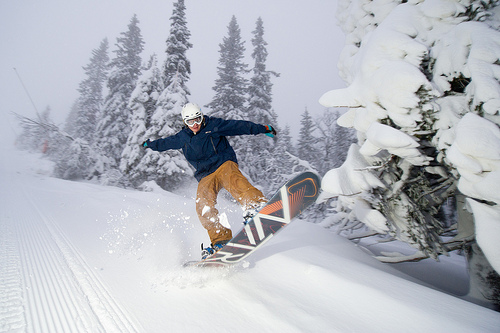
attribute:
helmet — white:
[175, 99, 204, 122]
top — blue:
[124, 114, 273, 174]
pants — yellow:
[191, 163, 264, 247]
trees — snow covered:
[21, 13, 302, 202]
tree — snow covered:
[309, 5, 496, 297]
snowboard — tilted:
[183, 160, 320, 283]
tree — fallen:
[10, 101, 107, 184]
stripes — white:
[233, 213, 282, 258]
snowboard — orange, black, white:
[184, 170, 319, 270]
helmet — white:
[175, 104, 201, 123]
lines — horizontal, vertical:
[4, 170, 164, 330]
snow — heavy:
[360, 41, 406, 121]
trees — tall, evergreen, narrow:
[17, 5, 201, 187]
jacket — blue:
[142, 108, 271, 184]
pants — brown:
[188, 161, 262, 244]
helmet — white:
[179, 99, 202, 126]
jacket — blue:
[135, 115, 280, 176]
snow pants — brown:
[193, 161, 265, 259]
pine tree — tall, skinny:
[97, 6, 149, 176]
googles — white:
[181, 110, 208, 130]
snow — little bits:
[102, 204, 196, 262]